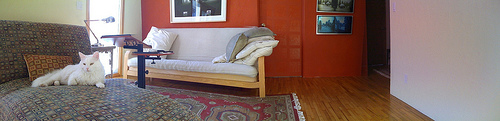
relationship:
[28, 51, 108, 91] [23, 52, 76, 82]
cat next to pillow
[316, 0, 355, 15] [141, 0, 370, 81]
picture on wall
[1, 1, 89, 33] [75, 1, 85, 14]
wall has light switch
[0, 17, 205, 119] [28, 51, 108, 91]
bed with cat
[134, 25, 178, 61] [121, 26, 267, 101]
pillow on futon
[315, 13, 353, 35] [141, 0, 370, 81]
picture on wall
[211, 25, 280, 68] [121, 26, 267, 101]
pillows on futon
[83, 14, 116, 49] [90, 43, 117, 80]
lamp on table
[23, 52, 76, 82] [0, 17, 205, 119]
pillow on bed